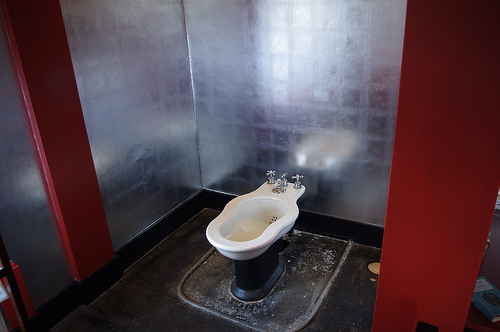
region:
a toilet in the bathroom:
[188, 159, 323, 308]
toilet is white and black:
[196, 158, 319, 310]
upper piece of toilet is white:
[200, 160, 315, 268]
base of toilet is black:
[226, 255, 301, 310]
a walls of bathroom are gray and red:
[0, 0, 499, 328]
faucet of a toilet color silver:
[274, 167, 291, 189]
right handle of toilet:
[286, 166, 307, 191]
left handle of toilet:
[261, 161, 278, 183]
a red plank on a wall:
[3, 2, 125, 285]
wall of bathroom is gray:
[103, 0, 387, 225]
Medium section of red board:
[418, 93, 467, 231]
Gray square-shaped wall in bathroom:
[255, 35, 326, 95]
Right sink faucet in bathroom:
[290, 170, 300, 186]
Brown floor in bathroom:
[132, 291, 159, 314]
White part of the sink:
[233, 204, 270, 239]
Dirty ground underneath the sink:
[287, 253, 326, 283]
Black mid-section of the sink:
[238, 264, 269, 286]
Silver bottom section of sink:
[233, 287, 270, 299]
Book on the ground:
[474, 277, 499, 319]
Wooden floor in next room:
[491, 254, 497, 270]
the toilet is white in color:
[203, 158, 335, 278]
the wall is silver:
[110, 77, 187, 179]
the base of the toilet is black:
[221, 254, 298, 307]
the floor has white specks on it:
[293, 235, 335, 277]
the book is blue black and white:
[466, 260, 496, 320]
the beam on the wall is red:
[11, 65, 121, 256]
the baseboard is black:
[112, 215, 192, 265]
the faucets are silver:
[260, 160, 320, 205]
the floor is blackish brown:
[105, 292, 171, 322]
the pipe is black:
[3, 240, 28, 326]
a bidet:
[140, 127, 343, 299]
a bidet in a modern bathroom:
[28, 17, 488, 254]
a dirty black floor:
[138, 268, 239, 329]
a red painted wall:
[370, 47, 468, 262]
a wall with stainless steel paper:
[88, 31, 229, 172]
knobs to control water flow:
[262, 164, 324, 194]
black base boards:
[78, 262, 141, 306]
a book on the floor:
[462, 277, 497, 314]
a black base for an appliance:
[222, 267, 304, 304]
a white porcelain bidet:
[147, 132, 309, 302]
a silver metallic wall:
[188, 9, 391, 171]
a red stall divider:
[388, 22, 469, 322]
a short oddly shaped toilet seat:
[189, 164, 312, 266]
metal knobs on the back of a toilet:
[261, 155, 310, 190]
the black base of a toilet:
[190, 244, 306, 309]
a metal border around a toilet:
[317, 240, 348, 278]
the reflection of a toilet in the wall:
[278, 112, 366, 194]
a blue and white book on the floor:
[471, 273, 498, 327]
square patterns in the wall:
[75, 22, 184, 122]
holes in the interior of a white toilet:
[263, 215, 278, 225]